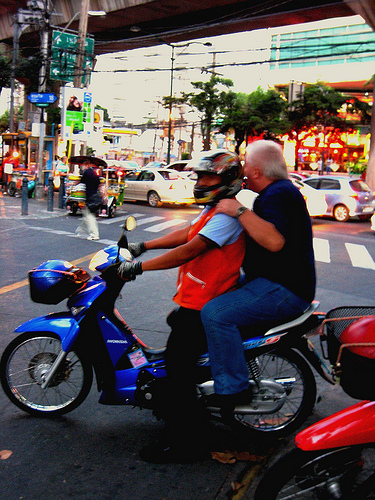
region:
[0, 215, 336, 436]
a blue motorcycle in the street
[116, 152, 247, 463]
a man wearing a red vest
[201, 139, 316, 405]
a man wearing a navy blue shirt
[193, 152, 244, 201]
a black motorcycle helmet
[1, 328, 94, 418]
the front wheel on a motorcycle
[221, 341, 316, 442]
the rear wheel on a motorcycle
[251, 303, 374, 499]
the front of a red motorcycle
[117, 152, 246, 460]
a man wearing black pants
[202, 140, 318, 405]
a man wearing a pair of jeans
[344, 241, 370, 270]
white square on road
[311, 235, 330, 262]
white square on road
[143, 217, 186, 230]
white square on road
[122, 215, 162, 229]
white square on road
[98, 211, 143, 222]
white square on road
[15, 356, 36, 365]
metal spoke on tire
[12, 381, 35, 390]
metal spoke on tire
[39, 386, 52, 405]
metal spoke on tire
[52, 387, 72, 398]
metal spoke on tire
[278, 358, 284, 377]
metal spoke on tire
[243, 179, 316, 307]
navy blue shirt on man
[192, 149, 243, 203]
helmet on man's head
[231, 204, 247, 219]
watch on man's wrist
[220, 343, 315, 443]
rear tire on motorcycle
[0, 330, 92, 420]
front tire on motorcycle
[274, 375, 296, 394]
exhaust pipe on motorcycle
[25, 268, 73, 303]
black basket on front of motorcycle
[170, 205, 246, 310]
red vest on man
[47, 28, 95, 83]
green road sign hanging over street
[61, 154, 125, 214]
food cart being pushed down street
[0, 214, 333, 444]
a blue motorcycle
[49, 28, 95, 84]
a green traffic sign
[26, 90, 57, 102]
a blue traffic sign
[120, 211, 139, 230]
rearview mirror of the motorcycle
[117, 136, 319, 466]
two men on the motorcycle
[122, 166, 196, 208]
a white sedan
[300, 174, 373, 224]
a silver hatchback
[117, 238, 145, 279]
black gloves on the motorcycle driver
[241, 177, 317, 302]
a black tshirt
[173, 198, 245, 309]
red vest over a blue tshirt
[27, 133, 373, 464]
Two men riding a motor bike.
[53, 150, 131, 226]
Man attending a food stand.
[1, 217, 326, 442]
Blue motor bike.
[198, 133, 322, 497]
Old man on the back of a motor bike.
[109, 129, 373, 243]
Cars waiting in traffic.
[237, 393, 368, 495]
Tire of a red motor bike.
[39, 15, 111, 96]
Green street signs.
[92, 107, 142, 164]
Gas Station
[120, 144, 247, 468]
Man wearing on a motor bike wearing a helmet.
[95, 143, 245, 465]
Man wearing a helmet.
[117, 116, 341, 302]
two people on bike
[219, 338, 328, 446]
back tire of bike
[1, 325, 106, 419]
front tire of bike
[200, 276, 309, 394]
a pair of blue jeans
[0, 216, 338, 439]
a blue motorcycle on street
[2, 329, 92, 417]
a motorcycle front tire